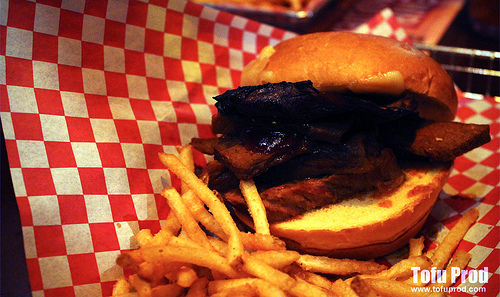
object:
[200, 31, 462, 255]
sandwich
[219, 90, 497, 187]
meat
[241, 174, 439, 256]
bun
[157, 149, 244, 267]
fries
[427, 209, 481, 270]
fries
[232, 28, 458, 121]
bun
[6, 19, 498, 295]
wrapper